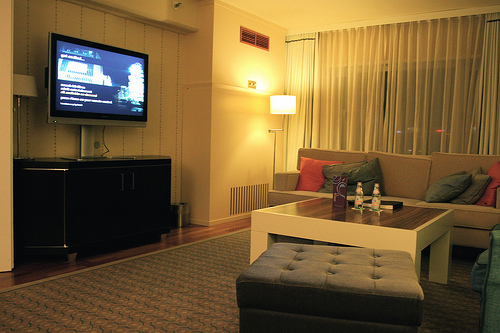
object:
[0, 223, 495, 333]
floor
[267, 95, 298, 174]
lamp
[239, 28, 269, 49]
vent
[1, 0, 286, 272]
wall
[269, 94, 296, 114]
lamp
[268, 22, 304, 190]
corner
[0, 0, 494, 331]
room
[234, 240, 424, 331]
foot rest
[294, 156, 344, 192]
pink pillow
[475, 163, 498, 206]
pink pillow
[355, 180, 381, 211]
bottles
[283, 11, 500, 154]
curtains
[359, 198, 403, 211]
items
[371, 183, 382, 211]
items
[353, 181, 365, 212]
items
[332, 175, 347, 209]
items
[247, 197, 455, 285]
table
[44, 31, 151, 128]
television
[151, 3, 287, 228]
wall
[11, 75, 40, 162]
desk lamp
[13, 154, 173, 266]
stand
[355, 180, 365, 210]
bottled drink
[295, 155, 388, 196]
pillows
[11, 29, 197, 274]
entertainment center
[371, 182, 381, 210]
water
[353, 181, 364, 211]
water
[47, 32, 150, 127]
tv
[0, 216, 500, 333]
ground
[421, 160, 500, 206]
pillows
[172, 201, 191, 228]
trashcan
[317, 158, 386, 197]
pillow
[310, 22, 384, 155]
surtain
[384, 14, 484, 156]
surtain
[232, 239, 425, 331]
ottoman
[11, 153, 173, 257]
cabinet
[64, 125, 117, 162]
stand